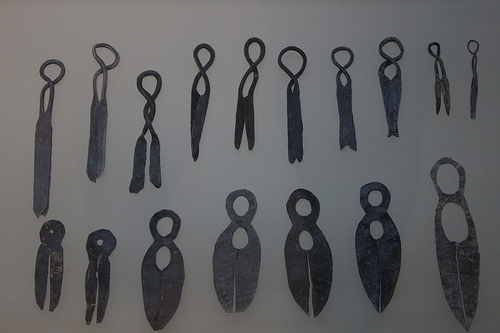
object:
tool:
[355, 180, 401, 313]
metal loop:
[136, 69, 162, 104]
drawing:
[235, 37, 266, 153]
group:
[25, 151, 498, 321]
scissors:
[187, 43, 218, 164]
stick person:
[141, 208, 184, 328]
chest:
[151, 242, 173, 271]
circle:
[231, 195, 250, 216]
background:
[5, 19, 488, 316]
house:
[6, 6, 486, 331]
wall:
[412, 117, 429, 159]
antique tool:
[273, 45, 308, 164]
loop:
[276, 45, 308, 76]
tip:
[143, 308, 185, 331]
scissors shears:
[231, 35, 265, 152]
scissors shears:
[210, 186, 265, 314]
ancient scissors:
[31, 59, 68, 220]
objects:
[330, 46, 359, 152]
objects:
[32, 216, 67, 313]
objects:
[284, 187, 335, 320]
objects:
[430, 157, 481, 332]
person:
[81, 227, 116, 325]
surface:
[31, 12, 491, 309]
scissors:
[232, 37, 269, 154]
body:
[129, 69, 164, 195]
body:
[426, 41, 452, 117]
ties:
[74, 75, 447, 185]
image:
[0, 4, 493, 333]